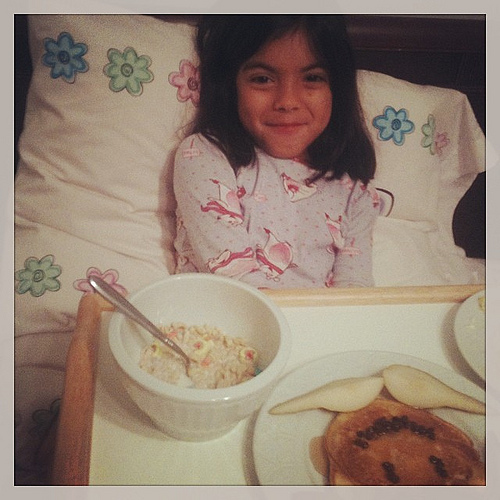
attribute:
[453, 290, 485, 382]
plate — white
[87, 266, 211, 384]
spoon — silver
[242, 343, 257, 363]
marshmallow — colorful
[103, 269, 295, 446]
bowl — white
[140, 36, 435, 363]
girl — smiling 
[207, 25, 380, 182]
hair — long , dark 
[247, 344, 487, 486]
plate — white 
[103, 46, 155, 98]
flower — green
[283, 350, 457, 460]
slices — fruit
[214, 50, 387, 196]
girl — lying down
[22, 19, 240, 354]
pillowcase — floral, bordered 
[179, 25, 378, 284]
girl — little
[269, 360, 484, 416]
pear — cut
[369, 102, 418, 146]
flower — blue